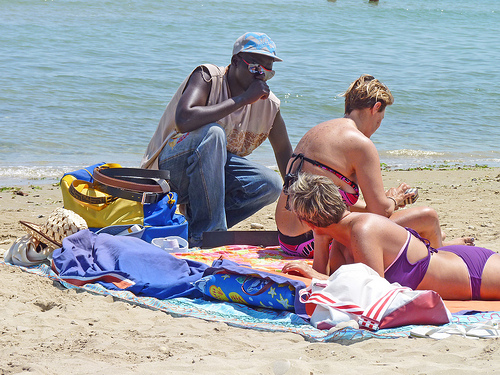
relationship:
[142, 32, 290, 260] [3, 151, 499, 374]
man gathered on beach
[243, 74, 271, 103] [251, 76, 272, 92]
hand in front of mouth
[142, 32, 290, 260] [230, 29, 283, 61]
man in cap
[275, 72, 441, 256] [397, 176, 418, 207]
woman holds cell phone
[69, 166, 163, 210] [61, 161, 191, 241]
belts on bag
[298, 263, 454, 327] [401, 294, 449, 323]
bag h red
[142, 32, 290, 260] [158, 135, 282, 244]
man wears jeans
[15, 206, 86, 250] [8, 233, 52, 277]
hat on blanket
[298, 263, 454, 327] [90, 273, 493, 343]
bag on blanket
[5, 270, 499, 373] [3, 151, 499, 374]
sand on beach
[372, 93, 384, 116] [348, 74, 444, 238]
ear on right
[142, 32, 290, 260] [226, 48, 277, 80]
man wears sunglasses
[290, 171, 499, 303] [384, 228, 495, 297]
woman wear bikini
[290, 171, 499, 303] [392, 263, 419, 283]
woman wears purple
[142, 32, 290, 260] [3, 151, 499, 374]
man at beach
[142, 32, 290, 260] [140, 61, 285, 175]
man wears a sleeveless top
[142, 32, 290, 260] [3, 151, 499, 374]
man on beach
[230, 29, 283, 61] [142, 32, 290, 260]
cap worn by a man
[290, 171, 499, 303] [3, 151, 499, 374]
woman sit on beach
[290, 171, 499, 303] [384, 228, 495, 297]
woman wearing a bikini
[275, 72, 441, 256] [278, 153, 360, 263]
woman wearing a pink bikini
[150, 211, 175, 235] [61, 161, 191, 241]
blue on bag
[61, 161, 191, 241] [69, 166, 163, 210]
bag under belts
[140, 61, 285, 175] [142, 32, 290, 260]
shirt worn by man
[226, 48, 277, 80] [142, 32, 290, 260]
sunglasses worn by man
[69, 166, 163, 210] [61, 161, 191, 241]
belts are laying on bag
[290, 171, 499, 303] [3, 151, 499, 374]
woman laying on beach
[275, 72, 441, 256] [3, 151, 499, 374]
woman sitting on beach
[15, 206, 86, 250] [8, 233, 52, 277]
hat sits on towels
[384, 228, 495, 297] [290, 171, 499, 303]
bikini worn by woman